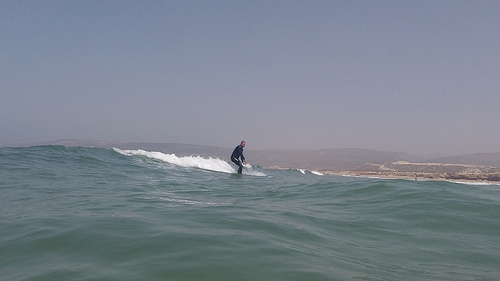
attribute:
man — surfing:
[229, 139, 256, 175]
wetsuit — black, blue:
[232, 147, 246, 173]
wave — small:
[104, 144, 235, 175]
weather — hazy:
[3, 10, 491, 270]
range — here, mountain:
[130, 135, 496, 170]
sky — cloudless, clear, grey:
[10, 4, 497, 156]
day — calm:
[2, 5, 496, 275]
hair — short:
[238, 140, 248, 145]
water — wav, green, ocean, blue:
[5, 145, 483, 276]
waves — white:
[110, 136, 232, 178]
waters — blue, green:
[0, 142, 499, 277]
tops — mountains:
[108, 133, 500, 164]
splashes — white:
[260, 165, 330, 178]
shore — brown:
[107, 142, 491, 196]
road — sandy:
[369, 157, 483, 170]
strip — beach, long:
[254, 167, 494, 188]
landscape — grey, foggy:
[38, 130, 499, 181]